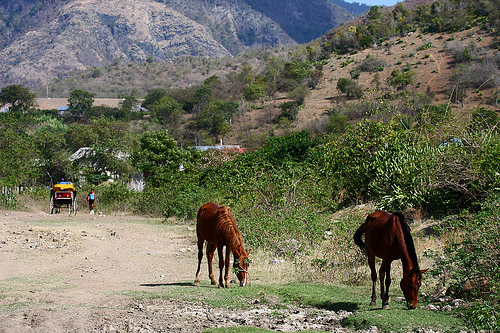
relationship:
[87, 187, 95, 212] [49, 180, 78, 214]
woman standing next to carriage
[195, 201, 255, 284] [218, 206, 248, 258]
horse has mane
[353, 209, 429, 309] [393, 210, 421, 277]
horse has mane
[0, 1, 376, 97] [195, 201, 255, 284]
mountains behind horse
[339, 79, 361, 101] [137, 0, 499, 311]
shrub on side of hill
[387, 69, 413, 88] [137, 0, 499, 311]
shrub on side of hill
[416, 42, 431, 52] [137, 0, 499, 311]
shrub on side of hill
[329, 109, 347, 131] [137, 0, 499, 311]
shrub on side of hill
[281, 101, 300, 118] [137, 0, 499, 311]
shrub on side of hill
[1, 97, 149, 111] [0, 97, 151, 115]
roof of building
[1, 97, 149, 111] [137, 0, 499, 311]
roof behind hill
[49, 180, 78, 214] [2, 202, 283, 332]
carriage on side of dirt road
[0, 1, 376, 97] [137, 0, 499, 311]
mountains behind hill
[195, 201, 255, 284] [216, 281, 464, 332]
horse grazing in grass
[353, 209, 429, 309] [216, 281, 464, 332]
horse grazing in grass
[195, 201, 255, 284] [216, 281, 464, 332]
horse eating grass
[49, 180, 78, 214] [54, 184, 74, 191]
carriage has load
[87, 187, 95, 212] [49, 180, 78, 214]
woman walking beside carriage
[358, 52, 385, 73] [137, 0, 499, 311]
shrub on side of hill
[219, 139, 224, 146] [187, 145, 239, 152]
stack on top of roof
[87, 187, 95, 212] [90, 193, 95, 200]
woman wearing shirt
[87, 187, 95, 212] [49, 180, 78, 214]
woman next to carriage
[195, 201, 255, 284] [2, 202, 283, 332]
horse grazing next to dirt road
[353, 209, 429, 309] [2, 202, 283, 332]
horse grazing next to dirt road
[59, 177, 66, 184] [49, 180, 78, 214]
man driving carriage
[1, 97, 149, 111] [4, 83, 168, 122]
roof beyond trees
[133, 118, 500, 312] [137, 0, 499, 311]
vegetation borders hill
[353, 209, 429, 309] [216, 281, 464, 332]
horse eating grass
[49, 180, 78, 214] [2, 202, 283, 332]
carriage on top of dirt road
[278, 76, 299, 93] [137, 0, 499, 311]
shrub growing on hill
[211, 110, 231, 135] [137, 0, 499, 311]
shrub growing on hill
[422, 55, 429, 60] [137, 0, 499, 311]
shrub growing on hill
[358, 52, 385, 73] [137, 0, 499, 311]
shrub growing on hill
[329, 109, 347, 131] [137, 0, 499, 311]
shrub growing on hill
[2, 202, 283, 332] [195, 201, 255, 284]
dirt road under horse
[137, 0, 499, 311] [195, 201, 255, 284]
hill behind horse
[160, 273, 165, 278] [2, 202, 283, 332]
rock on top of dirt road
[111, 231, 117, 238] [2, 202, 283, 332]
rock on top of dirt road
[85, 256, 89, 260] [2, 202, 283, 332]
rock on top of dirt road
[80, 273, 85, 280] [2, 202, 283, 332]
rock on top of dirt road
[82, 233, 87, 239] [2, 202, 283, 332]
rock on top of dirt road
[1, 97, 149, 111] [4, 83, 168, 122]
roof behind trees